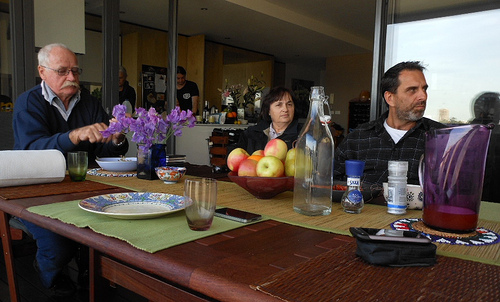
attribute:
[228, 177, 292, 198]
bowl — wooden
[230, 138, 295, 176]
fruit — fresh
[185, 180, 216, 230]
glass — empty, clear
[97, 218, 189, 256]
mat — green, placemat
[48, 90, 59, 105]
shirt — blue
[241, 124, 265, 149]
shirt — black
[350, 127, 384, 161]
shirt — plaid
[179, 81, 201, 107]
shirt — black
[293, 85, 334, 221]
caraffe — empty, tall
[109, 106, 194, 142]
flowers — purple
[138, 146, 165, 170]
vase — blue, small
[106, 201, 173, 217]
plate — white, blue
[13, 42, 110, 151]
man — old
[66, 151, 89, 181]
glass — green, empty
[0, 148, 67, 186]
towels — white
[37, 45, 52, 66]
hair — white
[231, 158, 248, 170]
apple — red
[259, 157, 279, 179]
apple — yellow, shiny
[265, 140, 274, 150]
apple — red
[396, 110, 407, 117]
beard — black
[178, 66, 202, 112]
person — standing